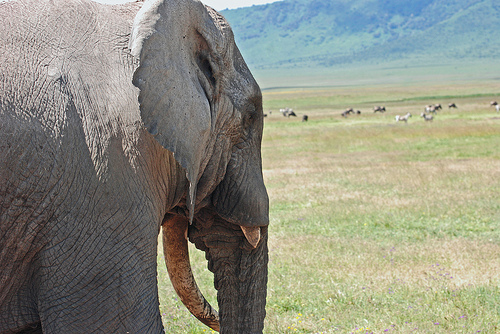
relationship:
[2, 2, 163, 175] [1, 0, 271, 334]
light on elephant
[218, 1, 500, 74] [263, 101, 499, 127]
hill behind animals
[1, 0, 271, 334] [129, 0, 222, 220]
elephant has ear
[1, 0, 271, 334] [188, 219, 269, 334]
elephant has trunk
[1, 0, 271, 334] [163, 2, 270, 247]
elephant has head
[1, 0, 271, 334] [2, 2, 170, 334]
elephant has body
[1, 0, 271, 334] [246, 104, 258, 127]
elephant has eye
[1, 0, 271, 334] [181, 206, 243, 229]
elephant has mouth